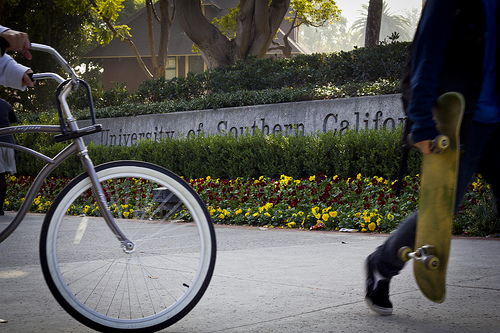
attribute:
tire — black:
[36, 153, 213, 330]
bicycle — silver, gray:
[4, 45, 300, 328]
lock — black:
[47, 74, 124, 151]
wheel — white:
[421, 136, 450, 155]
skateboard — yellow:
[400, 76, 472, 309]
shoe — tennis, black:
[340, 239, 409, 332]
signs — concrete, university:
[95, 93, 416, 165]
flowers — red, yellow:
[231, 173, 406, 241]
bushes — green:
[176, 41, 409, 108]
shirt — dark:
[414, 16, 497, 135]